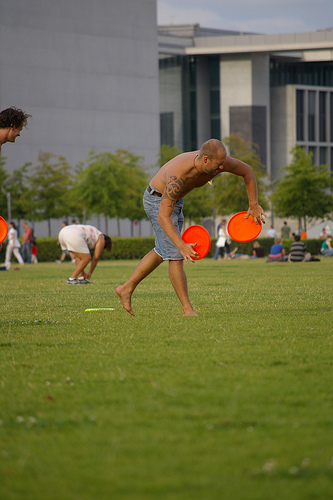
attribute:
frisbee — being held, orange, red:
[224, 210, 264, 244]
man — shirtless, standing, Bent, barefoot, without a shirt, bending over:
[112, 135, 269, 318]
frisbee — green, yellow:
[81, 304, 117, 315]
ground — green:
[0, 250, 332, 500]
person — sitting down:
[287, 231, 309, 264]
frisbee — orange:
[179, 224, 210, 261]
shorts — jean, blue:
[141, 181, 188, 262]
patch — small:
[0, 315, 80, 334]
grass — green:
[0, 257, 331, 500]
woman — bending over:
[55, 221, 112, 286]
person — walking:
[18, 216, 40, 265]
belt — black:
[145, 181, 163, 199]